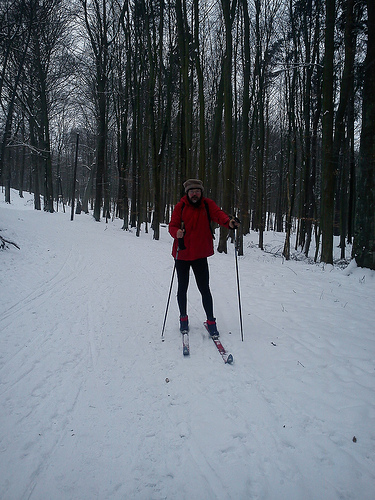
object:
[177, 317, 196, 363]
skis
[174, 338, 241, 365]
microwave door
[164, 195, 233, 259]
coat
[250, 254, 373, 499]
snow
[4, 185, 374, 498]
field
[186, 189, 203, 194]
glasses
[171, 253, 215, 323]
pants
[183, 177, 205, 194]
cap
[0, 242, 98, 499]
marks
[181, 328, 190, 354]
ski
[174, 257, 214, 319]
tights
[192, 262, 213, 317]
leg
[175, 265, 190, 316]
leg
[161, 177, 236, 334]
man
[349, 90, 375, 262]
tree trunks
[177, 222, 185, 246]
handle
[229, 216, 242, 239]
handle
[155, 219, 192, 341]
ski pole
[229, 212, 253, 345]
ski pole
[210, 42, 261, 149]
leaveless trees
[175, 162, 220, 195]
beanie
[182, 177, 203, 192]
hat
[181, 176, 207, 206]
head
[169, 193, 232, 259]
jacket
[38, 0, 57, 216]
trees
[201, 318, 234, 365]
ski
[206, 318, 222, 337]
foot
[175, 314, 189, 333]
foot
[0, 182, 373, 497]
ground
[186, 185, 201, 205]
face